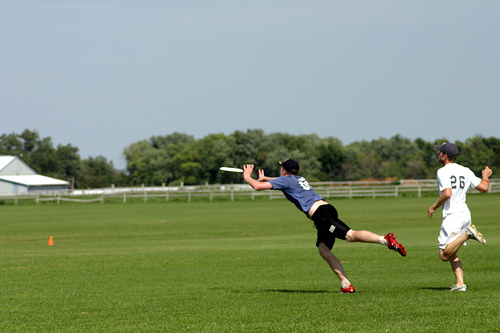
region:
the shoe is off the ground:
[383, 230, 410, 257]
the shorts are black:
[321, 216, 336, 233]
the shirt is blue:
[286, 182, 303, 201]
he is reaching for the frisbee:
[216, 158, 258, 178]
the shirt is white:
[445, 174, 459, 197]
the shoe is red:
[381, 226, 408, 260]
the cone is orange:
[42, 230, 59, 252]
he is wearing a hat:
[276, 154, 299, 177]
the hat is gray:
[431, 137, 456, 159]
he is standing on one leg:
[447, 269, 471, 296]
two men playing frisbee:
[216, 140, 493, 297]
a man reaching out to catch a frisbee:
[210, 153, 410, 297]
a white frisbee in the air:
[217, 162, 242, 174]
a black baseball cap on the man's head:
[276, 155, 299, 172]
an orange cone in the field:
[47, 235, 54, 247]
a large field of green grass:
[0, 193, 497, 332]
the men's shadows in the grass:
[210, 276, 460, 297]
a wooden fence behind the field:
[1, 179, 498, 204]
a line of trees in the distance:
[0, 127, 499, 182]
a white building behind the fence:
[0, 152, 80, 197]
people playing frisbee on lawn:
[216, 92, 497, 297]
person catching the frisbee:
[216, 136, 408, 308]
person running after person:
[427, 114, 497, 296]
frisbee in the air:
[213, 153, 245, 179]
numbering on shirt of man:
[451, 174, 474, 194]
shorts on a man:
[314, 203, 355, 244]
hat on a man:
[431, 137, 461, 159]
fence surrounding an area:
[12, 173, 495, 211]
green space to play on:
[13, 211, 468, 328]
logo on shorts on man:
[323, 225, 344, 233]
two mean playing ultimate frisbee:
[189, 113, 496, 322]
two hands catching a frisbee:
[217, 162, 278, 198]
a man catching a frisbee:
[211, 152, 409, 300]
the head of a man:
[275, 154, 300, 178]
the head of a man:
[434, 135, 461, 167]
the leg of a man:
[311, 245, 359, 292]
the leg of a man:
[343, 220, 411, 257]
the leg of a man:
[449, 254, 468, 298]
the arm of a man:
[475, 163, 494, 199]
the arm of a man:
[415, 184, 453, 219]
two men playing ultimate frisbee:
[207, 133, 493, 305]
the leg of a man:
[437, 223, 487, 260]